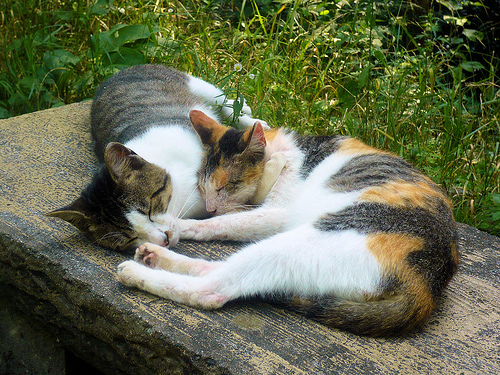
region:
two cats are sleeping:
[108, 112, 240, 234]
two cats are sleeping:
[70, 131, 291, 248]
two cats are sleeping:
[57, 158, 331, 326]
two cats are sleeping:
[91, 61, 363, 302]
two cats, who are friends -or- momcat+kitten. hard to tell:
[38, 51, 468, 360]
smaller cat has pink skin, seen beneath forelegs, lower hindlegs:
[105, 203, 287, 325]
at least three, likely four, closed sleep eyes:
[102, 172, 242, 260]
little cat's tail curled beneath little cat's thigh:
[231, 282, 438, 342]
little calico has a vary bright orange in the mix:
[185, 100, 465, 341]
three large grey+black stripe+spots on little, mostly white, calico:
[299, 128, 466, 291]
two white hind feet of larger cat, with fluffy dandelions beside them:
[214, 78, 275, 139]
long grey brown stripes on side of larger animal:
[85, 58, 207, 181]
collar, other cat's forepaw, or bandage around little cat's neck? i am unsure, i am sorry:
[244, 142, 287, 207]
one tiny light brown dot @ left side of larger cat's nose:
[160, 226, 177, 239]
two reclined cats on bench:
[68, 57, 448, 335]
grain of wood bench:
[433, 310, 487, 373]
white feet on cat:
[122, 241, 228, 309]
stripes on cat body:
[101, 70, 144, 137]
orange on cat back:
[365, 181, 433, 209]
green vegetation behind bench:
[299, 54, 444, 122]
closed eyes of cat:
[118, 202, 165, 252]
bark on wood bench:
[32, 267, 118, 347]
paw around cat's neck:
[256, 149, 291, 201]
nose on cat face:
[148, 224, 178, 244]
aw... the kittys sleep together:
[40, 62, 469, 354]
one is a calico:
[187, 97, 465, 333]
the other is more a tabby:
[66, 55, 243, 257]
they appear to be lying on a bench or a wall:
[11, 55, 487, 367]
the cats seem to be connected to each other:
[91, 105, 330, 310]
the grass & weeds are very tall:
[239, 33, 400, 105]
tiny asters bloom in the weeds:
[208, 45, 269, 83]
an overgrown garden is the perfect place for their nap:
[28, 20, 132, 57]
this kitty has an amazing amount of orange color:
[203, 110, 464, 332]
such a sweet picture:
[13, 3, 474, 373]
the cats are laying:
[109, 108, 470, 342]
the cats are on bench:
[17, 107, 445, 372]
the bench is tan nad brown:
[12, 112, 399, 369]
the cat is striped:
[270, 117, 450, 350]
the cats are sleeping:
[105, 91, 445, 343]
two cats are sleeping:
[94, 117, 450, 359]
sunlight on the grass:
[199, 28, 439, 146]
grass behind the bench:
[248, 18, 488, 193]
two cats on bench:
[81, 75, 483, 320]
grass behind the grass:
[104, 19, 492, 305]